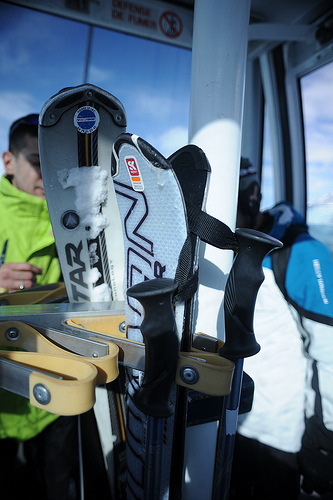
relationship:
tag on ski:
[70, 103, 100, 139] [34, 83, 146, 478]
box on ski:
[127, 155, 139, 176] [107, 124, 197, 466]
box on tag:
[130, 173, 144, 181] [120, 154, 147, 192]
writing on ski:
[114, 187, 164, 489] [107, 129, 190, 498]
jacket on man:
[0, 173, 84, 451] [2, 100, 107, 488]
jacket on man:
[268, 205, 332, 320] [231, 145, 330, 496]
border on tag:
[71, 105, 100, 134] [68, 105, 100, 135]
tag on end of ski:
[125, 153, 144, 193] [107, 129, 190, 498]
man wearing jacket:
[2, 100, 107, 488] [1, 165, 126, 445]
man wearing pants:
[0, 111, 111, 500] [8, 408, 109, 490]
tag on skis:
[124, 155, 145, 192] [40, 85, 157, 384]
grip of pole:
[126, 277, 180, 419] [111, 260, 254, 468]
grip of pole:
[126, 277, 180, 419] [120, 246, 256, 489]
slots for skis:
[3, 313, 150, 474] [124, 276, 241, 498]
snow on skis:
[58, 164, 110, 303] [32, 83, 257, 495]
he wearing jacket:
[8, 102, 117, 498] [1, 165, 126, 445]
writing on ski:
[113, 178, 166, 500] [107, 131, 188, 442]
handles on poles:
[125, 224, 288, 411] [121, 220, 283, 487]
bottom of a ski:
[168, 140, 209, 237] [174, 142, 212, 482]